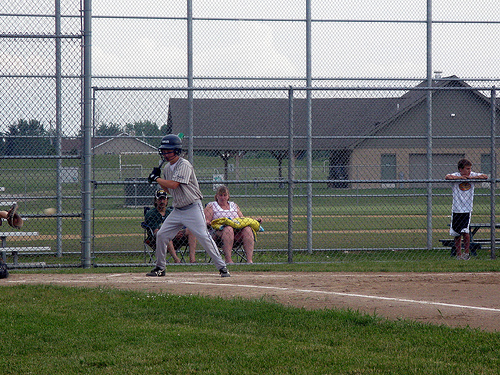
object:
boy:
[445, 157, 490, 262]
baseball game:
[0, 61, 500, 360]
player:
[145, 133, 231, 279]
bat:
[148, 132, 185, 184]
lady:
[202, 185, 266, 266]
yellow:
[210, 216, 260, 242]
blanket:
[211, 216, 261, 242]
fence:
[0, 0, 500, 271]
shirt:
[450, 172, 483, 214]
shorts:
[449, 212, 472, 237]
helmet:
[158, 134, 183, 150]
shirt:
[162, 156, 204, 208]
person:
[0, 180, 25, 279]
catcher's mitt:
[5, 200, 24, 231]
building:
[327, 70, 500, 191]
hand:
[147, 173, 160, 185]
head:
[157, 134, 184, 163]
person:
[144, 188, 201, 264]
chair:
[142, 206, 189, 264]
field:
[0, 249, 500, 371]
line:
[5, 279, 500, 314]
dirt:
[9, 270, 500, 333]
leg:
[222, 226, 235, 264]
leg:
[241, 225, 255, 263]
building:
[57, 124, 170, 157]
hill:
[57, 152, 186, 176]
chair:
[203, 203, 251, 263]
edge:
[48, 246, 51, 252]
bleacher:
[0, 245, 55, 256]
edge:
[36, 231, 38, 236]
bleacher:
[0, 231, 39, 237]